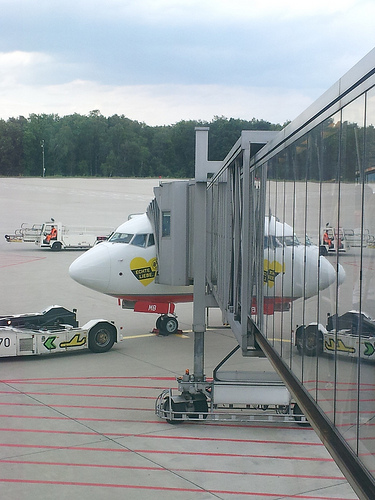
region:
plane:
[84, 209, 179, 309]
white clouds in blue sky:
[15, 20, 47, 56]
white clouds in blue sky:
[86, 37, 121, 56]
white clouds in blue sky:
[9, 26, 48, 80]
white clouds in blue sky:
[279, 47, 332, 108]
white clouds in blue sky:
[32, 28, 85, 93]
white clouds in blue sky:
[51, 13, 117, 73]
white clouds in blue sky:
[131, 28, 198, 71]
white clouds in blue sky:
[185, 16, 230, 76]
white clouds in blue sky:
[221, 38, 281, 78]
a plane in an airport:
[36, 178, 206, 342]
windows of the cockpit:
[104, 224, 157, 250]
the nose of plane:
[61, 238, 119, 293]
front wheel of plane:
[151, 308, 181, 338]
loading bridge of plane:
[145, 140, 370, 485]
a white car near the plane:
[3, 300, 127, 360]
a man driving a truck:
[7, 215, 93, 250]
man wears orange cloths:
[39, 220, 60, 245]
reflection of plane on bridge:
[265, 211, 345, 317]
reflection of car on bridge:
[287, 300, 370, 368]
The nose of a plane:
[64, 208, 154, 306]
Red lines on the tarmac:
[2, 375, 356, 498]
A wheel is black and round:
[83, 318, 119, 355]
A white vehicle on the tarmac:
[36, 215, 101, 257]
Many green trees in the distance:
[1, 107, 372, 183]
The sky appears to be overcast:
[1, 2, 372, 126]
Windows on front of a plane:
[105, 224, 157, 250]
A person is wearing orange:
[41, 222, 58, 247]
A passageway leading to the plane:
[143, 46, 373, 497]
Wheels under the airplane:
[148, 310, 182, 341]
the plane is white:
[65, 207, 189, 336]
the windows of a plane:
[97, 224, 154, 248]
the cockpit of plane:
[107, 203, 164, 276]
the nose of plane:
[60, 242, 119, 293]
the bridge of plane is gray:
[142, 107, 374, 480]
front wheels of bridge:
[154, 361, 308, 436]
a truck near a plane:
[2, 276, 169, 357]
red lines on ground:
[2, 359, 327, 497]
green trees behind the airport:
[7, 111, 252, 188]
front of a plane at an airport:
[64, 199, 171, 327]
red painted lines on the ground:
[22, 419, 104, 492]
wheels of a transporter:
[158, 389, 207, 431]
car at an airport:
[2, 303, 123, 365]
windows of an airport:
[252, 146, 346, 390]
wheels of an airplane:
[155, 312, 176, 334]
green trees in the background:
[54, 119, 165, 175]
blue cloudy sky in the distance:
[23, 10, 289, 102]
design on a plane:
[126, 254, 156, 291]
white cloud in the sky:
[0, 46, 40, 109]